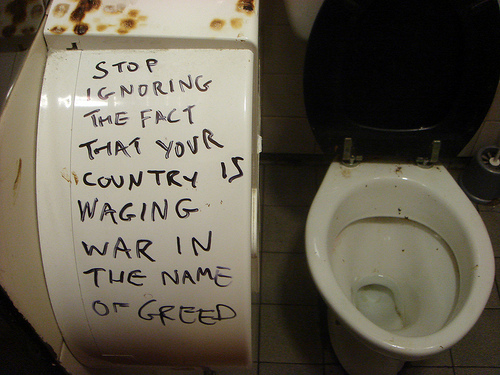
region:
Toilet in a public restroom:
[288, 0, 498, 372]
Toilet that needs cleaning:
[271, 3, 496, 368]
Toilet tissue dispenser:
[31, 22, 277, 367]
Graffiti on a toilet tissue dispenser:
[66, 55, 274, 371]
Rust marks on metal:
[35, 0, 260, 50]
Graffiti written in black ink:
[65, 50, 271, 371]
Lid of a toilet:
[297, 0, 497, 161]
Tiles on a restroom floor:
[260, 285, 348, 370]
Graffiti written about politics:
[53, 45, 259, 360]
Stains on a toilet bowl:
[302, 163, 498, 195]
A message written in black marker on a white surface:
[68, 53, 255, 335]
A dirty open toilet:
[305, 152, 499, 372]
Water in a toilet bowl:
[347, 265, 424, 330]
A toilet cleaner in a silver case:
[457, 143, 497, 203]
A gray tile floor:
[250, 229, 327, 371]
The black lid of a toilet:
[297, 2, 495, 169]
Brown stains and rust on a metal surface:
[45, 0, 159, 41]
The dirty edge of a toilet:
[331, 162, 425, 229]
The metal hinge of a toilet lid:
[417, 137, 448, 170]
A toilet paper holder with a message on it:
[35, 2, 282, 365]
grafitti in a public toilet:
[71, 47, 253, 350]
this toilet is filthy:
[311, 115, 492, 368]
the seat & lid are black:
[301, 15, 490, 217]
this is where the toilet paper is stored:
[71, 34, 271, 344]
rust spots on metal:
[58, 10, 240, 45]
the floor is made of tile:
[277, 288, 313, 364]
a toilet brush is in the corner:
[457, 143, 494, 199]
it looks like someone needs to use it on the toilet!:
[278, 137, 498, 364]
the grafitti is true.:
[43, 57, 264, 351]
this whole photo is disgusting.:
[33, 30, 498, 332]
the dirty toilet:
[284, 3, 497, 355]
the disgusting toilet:
[282, 2, 498, 359]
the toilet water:
[355, 272, 402, 319]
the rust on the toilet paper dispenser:
[50, 3, 262, 34]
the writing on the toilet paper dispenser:
[70, 56, 242, 343]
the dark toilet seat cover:
[305, 4, 480, 157]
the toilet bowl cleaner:
[468, 141, 498, 205]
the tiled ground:
[262, 186, 302, 367]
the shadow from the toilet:
[263, 252, 315, 359]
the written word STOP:
[92, 55, 159, 81]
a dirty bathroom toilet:
[284, 32, 497, 324]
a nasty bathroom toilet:
[254, 4, 499, 313]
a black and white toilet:
[254, 11, 443, 373]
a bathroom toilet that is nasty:
[280, 4, 465, 284]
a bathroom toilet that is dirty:
[291, 35, 490, 360]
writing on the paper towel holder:
[37, 25, 281, 371]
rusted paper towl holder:
[32, 3, 388, 370]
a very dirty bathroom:
[14, 7, 496, 351]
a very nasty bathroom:
[18, 7, 490, 342]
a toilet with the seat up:
[272, 27, 464, 369]